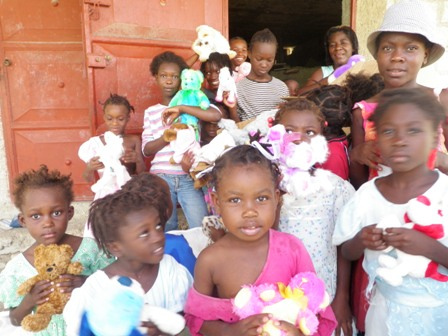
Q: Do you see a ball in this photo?
A: No, there are no balls.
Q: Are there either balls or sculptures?
A: No, there are no balls or sculptures.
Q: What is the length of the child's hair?
A: The hair is short.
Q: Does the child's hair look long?
A: No, the hair is short.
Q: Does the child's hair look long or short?
A: The hair is short.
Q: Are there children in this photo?
A: Yes, there is a child.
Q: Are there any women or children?
A: Yes, there is a child.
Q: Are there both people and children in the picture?
A: Yes, there are both a child and people.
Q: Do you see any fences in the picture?
A: No, there are no fences.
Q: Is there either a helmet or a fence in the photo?
A: No, there are no fences or helmets.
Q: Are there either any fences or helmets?
A: No, there are no fences or helmets.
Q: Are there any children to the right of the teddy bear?
A: Yes, there is a child to the right of the teddy bear.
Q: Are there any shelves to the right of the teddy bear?
A: No, there is a child to the right of the teddy bear.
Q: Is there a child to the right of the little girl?
A: Yes, there is a child to the right of the girl.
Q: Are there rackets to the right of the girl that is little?
A: No, there is a child to the right of the girl.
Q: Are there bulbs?
A: No, there are no bulbs.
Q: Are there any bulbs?
A: No, there are no bulbs.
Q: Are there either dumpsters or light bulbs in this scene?
A: No, there are no light bulbs or dumpsters.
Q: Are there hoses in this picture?
A: No, there are no hoses.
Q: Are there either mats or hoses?
A: No, there are no hoses or mats.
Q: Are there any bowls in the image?
A: No, there are no bowls.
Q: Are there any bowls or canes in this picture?
A: No, there are no bowls or canes.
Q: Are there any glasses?
A: No, there are no glasses.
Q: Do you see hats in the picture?
A: Yes, there is a hat.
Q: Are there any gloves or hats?
A: Yes, there is a hat.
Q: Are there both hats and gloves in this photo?
A: No, there is a hat but no gloves.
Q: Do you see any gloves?
A: No, there are no gloves.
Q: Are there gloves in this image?
A: No, there are no gloves.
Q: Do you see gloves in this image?
A: No, there are no gloves.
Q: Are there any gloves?
A: No, there are no gloves.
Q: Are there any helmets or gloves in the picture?
A: No, there are no gloves or helmets.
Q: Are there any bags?
A: No, there are no bags.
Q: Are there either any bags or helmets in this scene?
A: No, there are no bags or helmets.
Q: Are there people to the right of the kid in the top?
A: Yes, there is a person to the right of the kid.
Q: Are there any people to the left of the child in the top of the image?
A: No, the person is to the right of the child.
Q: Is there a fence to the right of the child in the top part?
A: No, there is a person to the right of the kid.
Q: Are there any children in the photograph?
A: Yes, there is a child.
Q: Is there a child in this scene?
A: Yes, there is a child.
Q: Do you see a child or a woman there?
A: Yes, there is a child.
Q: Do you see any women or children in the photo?
A: Yes, there is a child.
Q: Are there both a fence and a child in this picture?
A: No, there is a child but no fences.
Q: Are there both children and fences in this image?
A: No, there is a child but no fences.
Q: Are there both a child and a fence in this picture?
A: No, there is a child but no fences.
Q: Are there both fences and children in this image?
A: No, there is a child but no fences.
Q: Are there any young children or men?
A: Yes, there is a young child.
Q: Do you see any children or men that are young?
A: Yes, the child is young.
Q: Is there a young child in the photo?
A: Yes, there is a young child.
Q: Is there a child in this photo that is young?
A: Yes, there is a child that is young.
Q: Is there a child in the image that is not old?
A: Yes, there is an young child.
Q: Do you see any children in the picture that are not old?
A: Yes, there is an young child.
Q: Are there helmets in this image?
A: No, there are no helmets.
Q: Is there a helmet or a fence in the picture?
A: No, there are no helmets or fences.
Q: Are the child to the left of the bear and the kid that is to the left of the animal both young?
A: Yes, both the kid and the kid are young.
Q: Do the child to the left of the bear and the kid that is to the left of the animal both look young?
A: Yes, both the kid and the kid are young.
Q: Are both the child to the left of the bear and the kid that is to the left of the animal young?
A: Yes, both the kid and the kid are young.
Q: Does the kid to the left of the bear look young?
A: Yes, the kid is young.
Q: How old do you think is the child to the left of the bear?
A: The child is young.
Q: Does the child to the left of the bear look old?
A: No, the kid is young.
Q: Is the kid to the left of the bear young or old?
A: The kid is young.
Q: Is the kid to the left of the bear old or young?
A: The kid is young.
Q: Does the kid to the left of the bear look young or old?
A: The kid is young.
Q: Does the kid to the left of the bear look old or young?
A: The kid is young.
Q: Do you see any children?
A: Yes, there is a child.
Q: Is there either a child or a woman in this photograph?
A: Yes, there is a child.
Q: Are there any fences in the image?
A: No, there are no fences.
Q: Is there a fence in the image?
A: No, there are no fences.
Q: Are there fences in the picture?
A: No, there are no fences.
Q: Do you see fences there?
A: No, there are no fences.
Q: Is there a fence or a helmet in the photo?
A: No, there are no fences or helmets.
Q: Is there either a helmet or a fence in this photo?
A: No, there are no fences or helmets.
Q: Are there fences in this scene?
A: No, there are no fences.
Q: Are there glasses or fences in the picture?
A: No, there are no fences or glasses.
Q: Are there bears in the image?
A: Yes, there is a bear.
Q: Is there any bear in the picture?
A: Yes, there is a bear.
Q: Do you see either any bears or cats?
A: Yes, there is a bear.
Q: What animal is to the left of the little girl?
A: The animal is a bear.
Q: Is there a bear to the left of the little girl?
A: Yes, there is a bear to the left of the girl.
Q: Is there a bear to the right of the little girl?
A: No, the bear is to the left of the girl.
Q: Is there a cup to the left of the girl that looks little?
A: No, there is a bear to the left of the girl.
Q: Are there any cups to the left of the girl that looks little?
A: No, there is a bear to the left of the girl.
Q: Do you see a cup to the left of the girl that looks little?
A: No, there is a bear to the left of the girl.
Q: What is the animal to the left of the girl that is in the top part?
A: The animal is a bear.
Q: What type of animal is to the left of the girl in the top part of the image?
A: The animal is a bear.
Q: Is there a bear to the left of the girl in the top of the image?
A: Yes, there is a bear to the left of the girl.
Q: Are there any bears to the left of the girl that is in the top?
A: Yes, there is a bear to the left of the girl.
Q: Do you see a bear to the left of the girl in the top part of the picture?
A: Yes, there is a bear to the left of the girl.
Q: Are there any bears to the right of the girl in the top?
A: No, the bear is to the left of the girl.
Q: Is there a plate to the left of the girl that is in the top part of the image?
A: No, there is a bear to the left of the girl.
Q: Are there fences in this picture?
A: No, there are no fences.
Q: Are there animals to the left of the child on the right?
A: Yes, there is an animal to the left of the child.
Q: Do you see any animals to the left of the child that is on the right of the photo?
A: Yes, there is an animal to the left of the child.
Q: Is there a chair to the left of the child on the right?
A: No, there is an animal to the left of the child.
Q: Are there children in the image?
A: Yes, there is a child.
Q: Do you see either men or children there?
A: Yes, there is a child.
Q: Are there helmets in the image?
A: No, there are no helmets.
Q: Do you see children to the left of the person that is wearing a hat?
A: Yes, there is a child to the left of the person.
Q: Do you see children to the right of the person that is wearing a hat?
A: No, the child is to the left of the person.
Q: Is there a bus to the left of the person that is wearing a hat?
A: No, there is a child to the left of the person.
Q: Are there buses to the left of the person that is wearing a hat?
A: No, there is a child to the left of the person.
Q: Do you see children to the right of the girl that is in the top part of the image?
A: Yes, there is a child to the right of the girl.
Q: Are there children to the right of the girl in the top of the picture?
A: Yes, there is a child to the right of the girl.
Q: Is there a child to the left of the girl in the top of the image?
A: No, the child is to the right of the girl.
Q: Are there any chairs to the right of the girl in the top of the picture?
A: No, there is a child to the right of the girl.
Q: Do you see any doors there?
A: Yes, there is a door.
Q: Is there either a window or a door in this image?
A: Yes, there is a door.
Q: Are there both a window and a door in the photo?
A: No, there is a door but no windows.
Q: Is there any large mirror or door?
A: Yes, there is a large door.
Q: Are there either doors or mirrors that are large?
A: Yes, the door is large.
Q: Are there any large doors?
A: Yes, there is a large door.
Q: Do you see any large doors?
A: Yes, there is a large door.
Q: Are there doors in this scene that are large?
A: Yes, there is a door that is large.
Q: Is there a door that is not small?
A: Yes, there is a large door.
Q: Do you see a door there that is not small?
A: Yes, there is a large door.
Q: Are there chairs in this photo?
A: No, there are no chairs.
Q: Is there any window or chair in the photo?
A: No, there are no chairs or windows.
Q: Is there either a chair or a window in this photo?
A: No, there are no chairs or windows.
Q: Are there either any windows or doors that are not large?
A: No, there is a door but it is large.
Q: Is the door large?
A: Yes, the door is large.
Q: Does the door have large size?
A: Yes, the door is large.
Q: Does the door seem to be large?
A: Yes, the door is large.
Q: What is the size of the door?
A: The door is large.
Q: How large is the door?
A: The door is large.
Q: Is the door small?
A: No, the door is large.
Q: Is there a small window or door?
A: No, there is a door but it is large.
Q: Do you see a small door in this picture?
A: No, there is a door but it is large.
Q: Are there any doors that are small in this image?
A: No, there is a door but it is large.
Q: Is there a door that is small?
A: No, there is a door but it is large.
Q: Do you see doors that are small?
A: No, there is a door but it is large.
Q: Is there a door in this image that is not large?
A: No, there is a door but it is large.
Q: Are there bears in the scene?
A: Yes, there is a bear.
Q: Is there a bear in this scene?
A: Yes, there is a bear.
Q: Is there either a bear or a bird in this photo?
A: Yes, there is a bear.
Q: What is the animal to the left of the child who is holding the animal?
A: The animal is a bear.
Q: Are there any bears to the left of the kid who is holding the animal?
A: Yes, there is a bear to the left of the kid.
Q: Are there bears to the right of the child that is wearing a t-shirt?
A: No, the bear is to the left of the child.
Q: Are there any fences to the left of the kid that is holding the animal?
A: No, there is a bear to the left of the child.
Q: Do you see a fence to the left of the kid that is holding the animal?
A: No, there is a bear to the left of the child.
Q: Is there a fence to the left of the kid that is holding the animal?
A: No, there is a bear to the left of the child.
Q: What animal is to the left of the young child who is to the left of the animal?
A: The animal is a bear.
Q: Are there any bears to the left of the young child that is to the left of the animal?
A: Yes, there is a bear to the left of the kid.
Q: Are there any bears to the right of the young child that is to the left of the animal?
A: No, the bear is to the left of the child.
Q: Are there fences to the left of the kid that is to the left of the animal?
A: No, there is a bear to the left of the kid.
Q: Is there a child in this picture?
A: Yes, there is a child.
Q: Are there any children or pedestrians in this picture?
A: Yes, there is a child.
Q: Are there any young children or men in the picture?
A: Yes, there is a young child.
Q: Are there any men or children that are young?
A: Yes, the child is young.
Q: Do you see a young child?
A: Yes, there is a young child.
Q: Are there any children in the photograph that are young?
A: Yes, there is a child that is young.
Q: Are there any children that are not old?
A: Yes, there is an young child.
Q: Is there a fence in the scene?
A: No, there are no fences.